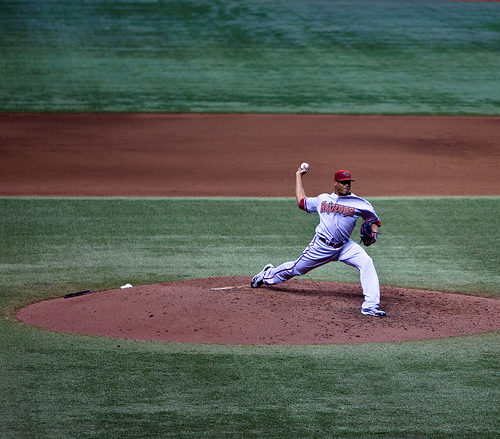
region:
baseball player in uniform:
[231, 110, 417, 340]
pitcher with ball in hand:
[240, 140, 390, 330]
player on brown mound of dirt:
[116, 130, 412, 380]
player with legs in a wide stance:
[240, 136, 395, 321]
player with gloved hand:
[235, 115, 410, 330]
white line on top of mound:
[190, 275, 275, 295]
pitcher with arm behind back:
[240, 125, 395, 330]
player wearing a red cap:
[265, 125, 410, 275]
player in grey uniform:
[240, 125, 395, 326]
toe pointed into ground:
[215, 193, 330, 311]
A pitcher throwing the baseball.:
[30, 103, 460, 386]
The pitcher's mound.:
[155, 261, 323, 343]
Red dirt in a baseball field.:
[51, 112, 222, 192]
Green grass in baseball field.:
[12, 332, 359, 431]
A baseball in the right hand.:
[291, 153, 314, 186]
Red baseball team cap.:
[331, 160, 355, 185]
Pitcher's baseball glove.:
[358, 215, 396, 250]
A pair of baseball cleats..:
[253, 260, 398, 320]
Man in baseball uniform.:
[243, 152, 408, 327]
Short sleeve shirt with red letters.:
[300, 181, 371, 236]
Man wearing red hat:
[306, 161, 371, 199]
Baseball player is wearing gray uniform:
[277, 161, 384, 336]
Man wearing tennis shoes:
[249, 243, 402, 359]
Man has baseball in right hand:
[272, 148, 357, 283]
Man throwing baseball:
[278, 155, 405, 322]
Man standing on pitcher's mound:
[118, 142, 419, 329]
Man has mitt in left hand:
[346, 205, 387, 290]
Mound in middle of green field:
[46, 230, 462, 405]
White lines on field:
[36, 165, 253, 230]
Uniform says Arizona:
[316, 165, 372, 265]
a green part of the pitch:
[226, 5, 422, 95]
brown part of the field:
[216, 290, 323, 341]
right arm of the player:
[289, 166, 306, 201]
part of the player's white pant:
[333, 247, 373, 309]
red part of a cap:
[335, 170, 353, 180]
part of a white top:
[327, 202, 344, 244]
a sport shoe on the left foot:
[356, 296, 386, 320]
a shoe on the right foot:
[253, 256, 269, 290]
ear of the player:
[330, 174, 337, 185]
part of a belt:
[319, 240, 342, 249]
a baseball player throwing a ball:
[188, 139, 440, 359]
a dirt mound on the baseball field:
[164, 290, 278, 341]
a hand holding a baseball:
[294, 153, 309, 176]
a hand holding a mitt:
[352, 212, 389, 244]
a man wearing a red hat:
[255, 168, 380, 325]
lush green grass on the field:
[106, 214, 226, 265]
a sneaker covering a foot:
[352, 296, 398, 322]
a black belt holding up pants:
[308, 241, 355, 248]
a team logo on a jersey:
[320, 200, 357, 222]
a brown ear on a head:
[334, 179, 339, 189]